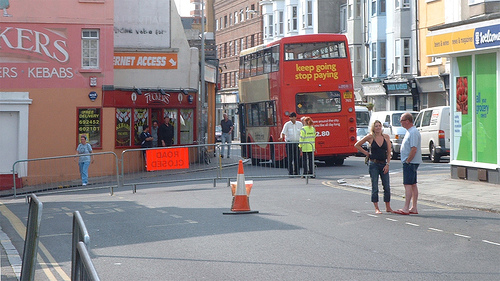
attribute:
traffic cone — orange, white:
[222, 158, 259, 214]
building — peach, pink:
[4, 2, 119, 191]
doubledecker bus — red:
[234, 25, 360, 168]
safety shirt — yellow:
[300, 124, 317, 152]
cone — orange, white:
[220, 156, 262, 219]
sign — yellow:
[297, 60, 338, 84]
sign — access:
[110, 47, 180, 72]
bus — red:
[208, 26, 374, 181]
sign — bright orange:
[131, 136, 211, 180]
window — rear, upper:
[278, 34, 345, 62]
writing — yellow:
[292, 60, 337, 80]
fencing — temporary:
[14, 138, 321, 196]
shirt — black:
[369, 139, 389, 162]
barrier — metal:
[11, 139, 314, 198]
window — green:
[451, 52, 485, 171]